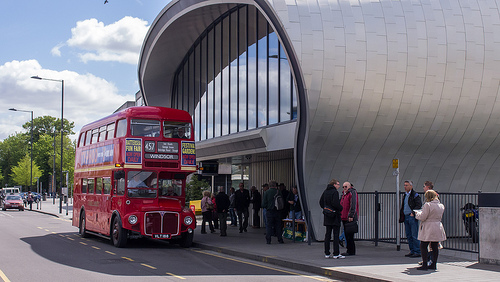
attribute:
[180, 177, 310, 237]
people — grouped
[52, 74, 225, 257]
bus — red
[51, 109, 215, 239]
bus — tall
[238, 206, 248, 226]
pants — dark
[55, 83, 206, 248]
bus — red, double decker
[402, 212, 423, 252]
pants — dark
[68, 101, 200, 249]
bus — large, double decker, two story, red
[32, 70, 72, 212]
light — large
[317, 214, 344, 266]
pants — dark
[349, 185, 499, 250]
fence — black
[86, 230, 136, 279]
lines — yellow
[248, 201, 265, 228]
pants — dark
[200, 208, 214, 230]
pants — dark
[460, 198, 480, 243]
motorcycle — parked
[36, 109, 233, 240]
bus — double decker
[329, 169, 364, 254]
jacket — red, grey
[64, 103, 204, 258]
bus — red, double decker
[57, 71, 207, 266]
bus — red